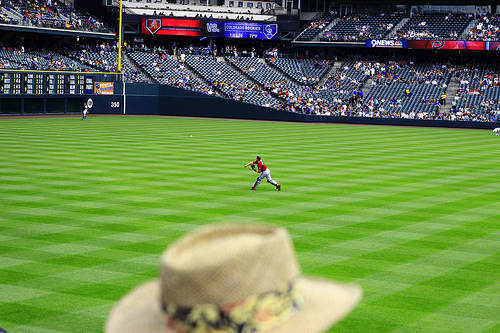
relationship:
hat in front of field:
[101, 218, 366, 331] [0, 115, 498, 332]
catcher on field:
[243, 155, 283, 193] [0, 115, 498, 332]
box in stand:
[223, 38, 263, 56] [0, 0, 497, 122]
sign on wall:
[92, 81, 116, 94] [1, 70, 306, 120]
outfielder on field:
[81, 99, 88, 121] [0, 115, 498, 332]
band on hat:
[163, 271, 306, 331] [101, 218, 366, 331]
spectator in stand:
[374, 96, 381, 107] [0, 0, 497, 122]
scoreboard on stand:
[3, 70, 87, 96] [0, 0, 497, 122]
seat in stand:
[405, 101, 411, 110] [0, 0, 497, 122]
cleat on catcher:
[274, 183, 281, 192] [243, 155, 283, 193]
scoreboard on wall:
[3, 70, 87, 96] [1, 70, 306, 120]